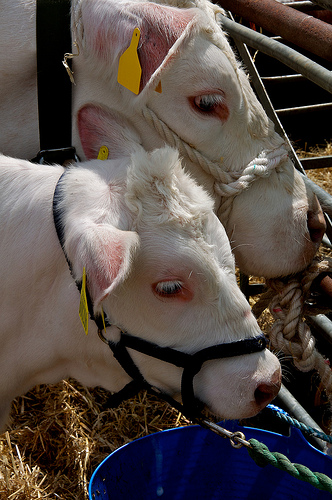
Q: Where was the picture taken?
A: On a farm.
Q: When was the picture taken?
A: Daytime.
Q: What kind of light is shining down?
A: Sunlight.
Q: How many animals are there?
A: Two.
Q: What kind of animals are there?
A: Cows.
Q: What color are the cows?
A: White.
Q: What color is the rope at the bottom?
A: Green.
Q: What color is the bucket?
A: Blue.